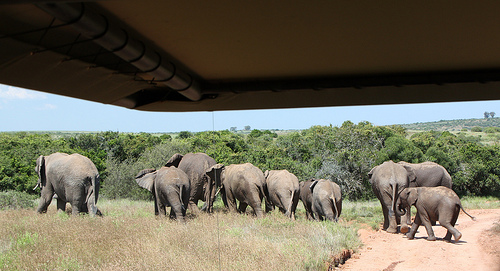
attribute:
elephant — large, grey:
[363, 155, 461, 241]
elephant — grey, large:
[299, 169, 351, 234]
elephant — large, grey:
[258, 156, 302, 238]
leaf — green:
[211, 137, 228, 159]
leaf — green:
[11, 139, 54, 164]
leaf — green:
[28, 129, 46, 149]